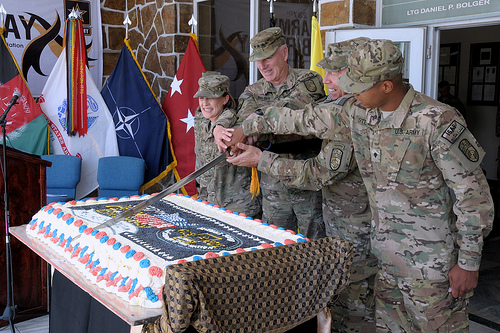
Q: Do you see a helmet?
A: No, there are no helmets.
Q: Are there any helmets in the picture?
A: No, there are no helmets.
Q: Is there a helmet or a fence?
A: No, there are no helmets or fences.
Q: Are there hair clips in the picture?
A: No, there are no hair clips.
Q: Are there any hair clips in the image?
A: No, there are no hair clips.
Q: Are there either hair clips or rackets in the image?
A: No, there are no hair clips or rackets.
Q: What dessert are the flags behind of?
A: The flags are behind the cake.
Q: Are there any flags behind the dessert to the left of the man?
A: Yes, there are flags behind the cake.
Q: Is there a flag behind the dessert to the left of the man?
A: Yes, there are flags behind the cake.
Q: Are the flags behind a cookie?
A: No, the flags are behind a cake.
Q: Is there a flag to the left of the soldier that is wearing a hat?
A: Yes, there are flags to the left of the soldier.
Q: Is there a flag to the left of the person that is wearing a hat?
A: Yes, there are flags to the left of the soldier.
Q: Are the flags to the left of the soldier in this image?
A: Yes, the flags are to the left of the soldier.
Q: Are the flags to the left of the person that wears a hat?
A: Yes, the flags are to the left of the soldier.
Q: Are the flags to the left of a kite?
A: No, the flags are to the left of the soldier.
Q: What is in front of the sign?
A: The flags are in front of the sign.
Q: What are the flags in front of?
A: The flags are in front of the sign.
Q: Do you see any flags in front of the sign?
A: Yes, there are flags in front of the sign.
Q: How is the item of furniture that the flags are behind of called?
A: The piece of furniture is a chair.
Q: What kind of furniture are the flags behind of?
A: The flags are behind the chair.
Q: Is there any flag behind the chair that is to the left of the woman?
A: Yes, there are flags behind the chair.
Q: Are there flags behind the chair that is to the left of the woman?
A: Yes, there are flags behind the chair.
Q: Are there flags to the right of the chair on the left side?
A: Yes, there are flags to the right of the chair.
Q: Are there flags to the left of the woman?
A: Yes, there are flags to the left of the woman.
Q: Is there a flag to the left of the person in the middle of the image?
A: Yes, there are flags to the left of the woman.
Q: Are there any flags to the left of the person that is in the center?
A: Yes, there are flags to the left of the woman.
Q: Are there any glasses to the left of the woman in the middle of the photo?
A: No, there are flags to the left of the woman.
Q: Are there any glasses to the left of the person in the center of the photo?
A: No, there are flags to the left of the woman.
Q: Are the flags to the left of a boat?
A: No, the flags are to the left of a woman.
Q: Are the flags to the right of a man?
A: No, the flags are to the left of a man.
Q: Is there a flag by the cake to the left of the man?
A: Yes, there are flags by the cake.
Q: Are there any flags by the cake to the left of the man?
A: Yes, there are flags by the cake.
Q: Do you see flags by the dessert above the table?
A: Yes, there are flags by the cake.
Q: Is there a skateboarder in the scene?
A: No, there are no skateboarders.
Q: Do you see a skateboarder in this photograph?
A: No, there are no skateboarders.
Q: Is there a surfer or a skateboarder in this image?
A: No, there are no skateboarders or surfers.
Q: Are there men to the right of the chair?
A: Yes, there is a man to the right of the chair.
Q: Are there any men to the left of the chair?
A: No, the man is to the right of the chair.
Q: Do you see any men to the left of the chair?
A: No, the man is to the right of the chair.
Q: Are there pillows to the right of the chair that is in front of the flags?
A: No, there is a man to the right of the chair.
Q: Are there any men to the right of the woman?
A: Yes, there is a man to the right of the woman.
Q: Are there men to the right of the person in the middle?
A: Yes, there is a man to the right of the woman.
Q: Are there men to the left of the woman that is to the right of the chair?
A: No, the man is to the right of the woman.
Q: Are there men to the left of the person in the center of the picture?
A: No, the man is to the right of the woman.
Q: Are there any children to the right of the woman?
A: No, there is a man to the right of the woman.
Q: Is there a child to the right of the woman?
A: No, there is a man to the right of the woman.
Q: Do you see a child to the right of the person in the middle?
A: No, there is a man to the right of the woman.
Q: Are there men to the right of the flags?
A: Yes, there is a man to the right of the flags.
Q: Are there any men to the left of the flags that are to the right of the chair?
A: No, the man is to the right of the flags.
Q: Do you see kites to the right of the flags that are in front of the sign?
A: No, there is a man to the right of the flags.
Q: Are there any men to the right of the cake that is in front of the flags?
A: Yes, there is a man to the right of the cake.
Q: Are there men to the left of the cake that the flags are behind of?
A: No, the man is to the right of the cake.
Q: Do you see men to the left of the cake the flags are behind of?
A: No, the man is to the right of the cake.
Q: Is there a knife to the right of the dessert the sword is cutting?
A: No, there is a man to the right of the cake.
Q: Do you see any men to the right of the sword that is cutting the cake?
A: Yes, there is a man to the right of the sword.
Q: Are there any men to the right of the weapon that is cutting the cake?
A: Yes, there is a man to the right of the sword.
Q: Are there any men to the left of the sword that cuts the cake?
A: No, the man is to the right of the sword.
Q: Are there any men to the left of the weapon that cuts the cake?
A: No, the man is to the right of the sword.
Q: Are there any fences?
A: No, there are no fences.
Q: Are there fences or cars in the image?
A: No, there are no fences or cars.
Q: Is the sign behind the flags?
A: Yes, the sign is behind the flags.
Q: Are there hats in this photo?
A: Yes, there is a hat.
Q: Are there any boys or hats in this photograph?
A: Yes, there is a hat.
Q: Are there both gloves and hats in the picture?
A: No, there is a hat but no gloves.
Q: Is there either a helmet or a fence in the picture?
A: No, there are no helmets or fences.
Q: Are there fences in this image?
A: No, there are no fences.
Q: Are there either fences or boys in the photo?
A: No, there are no fences or boys.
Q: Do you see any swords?
A: Yes, there is a sword.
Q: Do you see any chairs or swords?
A: Yes, there is a sword.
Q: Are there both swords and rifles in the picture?
A: No, there is a sword but no rifles.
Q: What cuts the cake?
A: The sword cuts the cake.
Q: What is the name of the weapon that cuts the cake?
A: The weapon is a sword.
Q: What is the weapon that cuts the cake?
A: The weapon is a sword.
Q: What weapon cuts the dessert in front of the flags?
A: The weapon is a sword.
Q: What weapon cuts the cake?
A: The weapon is a sword.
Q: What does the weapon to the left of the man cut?
A: The sword cuts the cake.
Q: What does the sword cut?
A: The sword cuts the cake.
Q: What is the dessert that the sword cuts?
A: The dessert is a cake.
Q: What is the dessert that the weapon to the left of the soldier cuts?
A: The dessert is a cake.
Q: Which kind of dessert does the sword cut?
A: The sword cuts the cake.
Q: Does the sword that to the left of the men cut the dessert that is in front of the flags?
A: Yes, the sword cuts the cake.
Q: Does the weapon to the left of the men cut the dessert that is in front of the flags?
A: Yes, the sword cuts the cake.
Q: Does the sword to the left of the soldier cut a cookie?
A: No, the sword cuts the cake.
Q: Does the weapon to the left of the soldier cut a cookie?
A: No, the sword cuts the cake.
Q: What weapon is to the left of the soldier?
A: The weapon is a sword.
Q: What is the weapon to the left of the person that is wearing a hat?
A: The weapon is a sword.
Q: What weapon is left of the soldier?
A: The weapon is a sword.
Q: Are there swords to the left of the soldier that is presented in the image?
A: Yes, there is a sword to the left of the soldier.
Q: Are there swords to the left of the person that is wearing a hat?
A: Yes, there is a sword to the left of the soldier.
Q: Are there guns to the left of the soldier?
A: No, there is a sword to the left of the soldier.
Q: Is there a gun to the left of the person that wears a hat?
A: No, there is a sword to the left of the soldier.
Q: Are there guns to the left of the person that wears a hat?
A: No, there is a sword to the left of the soldier.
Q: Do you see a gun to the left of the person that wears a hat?
A: No, there is a sword to the left of the soldier.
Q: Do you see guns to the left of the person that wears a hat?
A: No, there is a sword to the left of the soldier.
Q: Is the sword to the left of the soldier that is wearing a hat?
A: Yes, the sword is to the left of the soldier.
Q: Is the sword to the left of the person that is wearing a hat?
A: Yes, the sword is to the left of the soldier.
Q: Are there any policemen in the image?
A: No, there are no policemen.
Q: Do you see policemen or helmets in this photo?
A: No, there are no policemen or helmets.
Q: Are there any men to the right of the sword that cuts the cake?
A: Yes, there are men to the right of the sword.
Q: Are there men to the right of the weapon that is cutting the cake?
A: Yes, there are men to the right of the sword.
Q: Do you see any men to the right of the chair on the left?
A: Yes, there are men to the right of the chair.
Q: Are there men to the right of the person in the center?
A: Yes, there are men to the right of the woman.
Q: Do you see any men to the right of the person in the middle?
A: Yes, there are men to the right of the woman.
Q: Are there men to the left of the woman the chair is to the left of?
A: No, the men are to the right of the woman.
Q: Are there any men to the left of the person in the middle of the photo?
A: No, the men are to the right of the woman.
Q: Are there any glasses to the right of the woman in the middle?
A: No, there are men to the right of the woman.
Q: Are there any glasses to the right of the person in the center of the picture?
A: No, there are men to the right of the woman.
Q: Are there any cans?
A: No, there are no cans.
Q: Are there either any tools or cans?
A: No, there are no cans or tools.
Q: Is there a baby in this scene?
A: No, there are no babies.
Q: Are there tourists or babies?
A: No, there are no babies or tourists.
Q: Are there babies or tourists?
A: No, there are no babies or tourists.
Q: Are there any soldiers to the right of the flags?
A: Yes, there is a soldier to the right of the flags.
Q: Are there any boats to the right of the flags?
A: No, there is a soldier to the right of the flags.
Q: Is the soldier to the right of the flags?
A: Yes, the soldier is to the right of the flags.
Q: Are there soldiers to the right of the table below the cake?
A: Yes, there is a soldier to the right of the table.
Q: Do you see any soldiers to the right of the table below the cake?
A: Yes, there is a soldier to the right of the table.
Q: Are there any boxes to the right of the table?
A: No, there is a soldier to the right of the table.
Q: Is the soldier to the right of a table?
A: Yes, the soldier is to the right of a table.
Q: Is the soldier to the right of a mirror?
A: No, the soldier is to the right of a table.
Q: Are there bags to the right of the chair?
A: No, there is a soldier to the right of the chair.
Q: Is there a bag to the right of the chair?
A: No, there is a soldier to the right of the chair.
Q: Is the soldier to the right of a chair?
A: Yes, the soldier is to the right of a chair.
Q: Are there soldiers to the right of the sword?
A: Yes, there is a soldier to the right of the sword.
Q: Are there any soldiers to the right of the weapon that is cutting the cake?
A: Yes, there is a soldier to the right of the sword.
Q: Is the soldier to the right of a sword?
A: Yes, the soldier is to the right of a sword.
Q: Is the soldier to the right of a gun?
A: No, the soldier is to the right of a sword.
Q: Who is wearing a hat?
A: The soldier is wearing a hat.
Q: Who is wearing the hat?
A: The soldier is wearing a hat.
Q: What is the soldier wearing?
A: The soldier is wearing a hat.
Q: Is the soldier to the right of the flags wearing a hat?
A: Yes, the soldier is wearing a hat.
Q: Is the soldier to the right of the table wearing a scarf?
A: No, the soldier is wearing a hat.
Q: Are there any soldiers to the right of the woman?
A: Yes, there is a soldier to the right of the woman.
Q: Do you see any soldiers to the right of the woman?
A: Yes, there is a soldier to the right of the woman.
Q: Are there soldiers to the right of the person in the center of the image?
A: Yes, there is a soldier to the right of the woman.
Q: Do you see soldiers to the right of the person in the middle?
A: Yes, there is a soldier to the right of the woman.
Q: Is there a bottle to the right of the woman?
A: No, there is a soldier to the right of the woman.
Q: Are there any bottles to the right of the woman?
A: No, there is a soldier to the right of the woman.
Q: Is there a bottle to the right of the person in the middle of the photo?
A: No, there is a soldier to the right of the woman.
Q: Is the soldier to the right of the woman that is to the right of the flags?
A: Yes, the soldier is to the right of the woman.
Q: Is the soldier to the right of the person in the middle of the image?
A: Yes, the soldier is to the right of the woman.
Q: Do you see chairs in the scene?
A: Yes, there is a chair.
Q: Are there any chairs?
A: Yes, there is a chair.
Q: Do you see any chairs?
A: Yes, there is a chair.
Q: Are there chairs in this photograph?
A: Yes, there is a chair.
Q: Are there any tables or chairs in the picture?
A: Yes, there is a chair.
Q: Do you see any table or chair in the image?
A: Yes, there is a chair.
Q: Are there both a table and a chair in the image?
A: Yes, there are both a chair and a table.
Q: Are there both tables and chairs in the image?
A: Yes, there are both a chair and a table.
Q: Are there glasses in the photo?
A: No, there are no glasses.